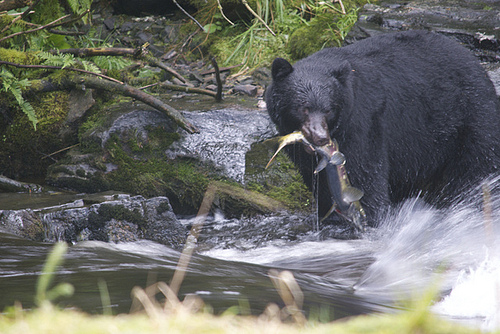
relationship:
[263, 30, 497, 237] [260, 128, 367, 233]
bear has fish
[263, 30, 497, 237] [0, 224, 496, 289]
bear in water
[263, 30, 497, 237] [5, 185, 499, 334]
bear looks at water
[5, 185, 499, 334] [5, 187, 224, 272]
water around rock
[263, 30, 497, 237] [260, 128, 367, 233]
bear has a fish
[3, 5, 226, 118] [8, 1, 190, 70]
branches are in back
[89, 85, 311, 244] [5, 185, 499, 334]
rocks are in water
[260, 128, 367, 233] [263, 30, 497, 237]
food for bear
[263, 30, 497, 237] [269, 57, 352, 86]
bear with two ears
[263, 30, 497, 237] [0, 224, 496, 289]
bear standing in water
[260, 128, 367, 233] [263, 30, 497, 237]
fish in mouth of bear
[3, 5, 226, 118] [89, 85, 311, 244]
branches over rocks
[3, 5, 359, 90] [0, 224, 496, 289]
grass in on side of water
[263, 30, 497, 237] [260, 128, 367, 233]
bear eats a fish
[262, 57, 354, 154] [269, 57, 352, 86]
head has black ears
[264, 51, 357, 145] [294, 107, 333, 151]
face has brown snout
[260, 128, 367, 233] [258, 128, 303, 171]
fish has a tail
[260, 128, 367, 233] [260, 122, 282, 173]
fish has a gray fin